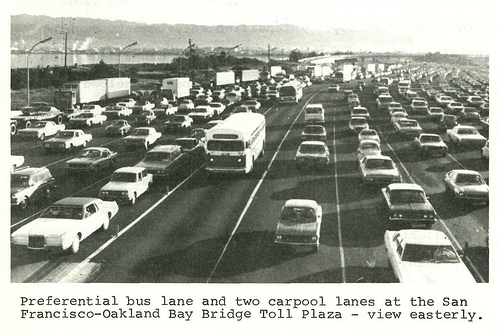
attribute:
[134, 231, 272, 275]
shadow — casting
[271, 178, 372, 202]
shadow — casting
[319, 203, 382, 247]
shadow — casting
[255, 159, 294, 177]
shadow — casting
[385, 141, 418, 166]
shadow — casting